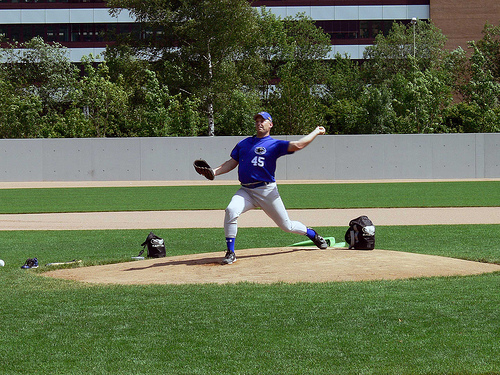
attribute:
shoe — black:
[222, 252, 236, 264]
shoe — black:
[310, 228, 327, 248]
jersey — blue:
[230, 136, 292, 185]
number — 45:
[252, 156, 265, 167]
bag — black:
[345, 215, 376, 250]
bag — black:
[139, 231, 166, 258]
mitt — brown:
[194, 160, 213, 180]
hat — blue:
[254, 112, 272, 121]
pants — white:
[224, 181, 306, 239]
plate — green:
[290, 235, 335, 246]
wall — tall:
[273, 131, 498, 183]